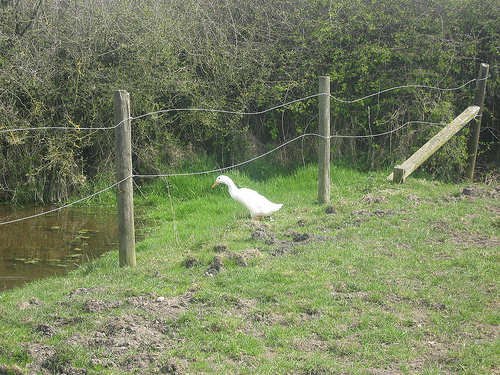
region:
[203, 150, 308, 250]
this is a duck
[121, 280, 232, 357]
a patch of grass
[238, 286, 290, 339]
a patch of grass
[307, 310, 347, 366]
a patch of grass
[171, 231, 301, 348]
a patch of grass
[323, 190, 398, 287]
a patch of grass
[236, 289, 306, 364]
a patch of grass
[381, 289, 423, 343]
a patch of grass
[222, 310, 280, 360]
a patch of grass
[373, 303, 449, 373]
a patch of grass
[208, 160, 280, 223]
white goose facing left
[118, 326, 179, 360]
brownish dead area of grass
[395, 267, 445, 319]
green area of grass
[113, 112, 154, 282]
brown wooden post holding fence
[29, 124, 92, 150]
barbed wire on post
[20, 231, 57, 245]
brown area of dirty water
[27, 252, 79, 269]
green leaves floating in dirty water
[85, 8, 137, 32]
bare limbs on tree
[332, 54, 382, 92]
green leafy tree limbs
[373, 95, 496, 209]
fallen board on right of photo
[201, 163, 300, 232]
a white duck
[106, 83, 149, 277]
a wooden fence pole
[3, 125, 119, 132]
a wire line of the fence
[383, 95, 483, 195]
a broken wood piece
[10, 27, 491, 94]
branches of trees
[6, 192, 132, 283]
a puddle of water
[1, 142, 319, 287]
a duck heading for a puddle of water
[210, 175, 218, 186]
the beak of the duck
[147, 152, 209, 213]
tall grass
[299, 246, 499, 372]
short grass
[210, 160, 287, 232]
Duck looking into the water.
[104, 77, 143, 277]
Wooden fence pole in the grass.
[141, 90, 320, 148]
Wire between the posts.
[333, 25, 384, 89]
Greenery in the distance.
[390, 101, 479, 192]
Wood pole that has fallen.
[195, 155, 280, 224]
Duck standing in bright green grass.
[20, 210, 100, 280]
Dirty brown water beside the grass.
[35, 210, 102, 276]
Leaves floating in the water.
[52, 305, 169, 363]
Mound of dried up grass.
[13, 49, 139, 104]
Tangled bushes on the other side.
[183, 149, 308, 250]
the duck is white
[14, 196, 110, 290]
the water is murky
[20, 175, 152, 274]
the water is murky